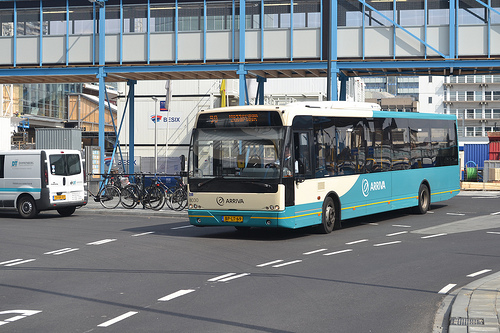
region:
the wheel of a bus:
[315, 190, 345, 235]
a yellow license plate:
[220, 208, 247, 226]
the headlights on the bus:
[260, 201, 282, 212]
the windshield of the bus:
[185, 122, 285, 183]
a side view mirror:
[175, 148, 190, 171]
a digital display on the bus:
[197, 107, 278, 128]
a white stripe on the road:
[152, 280, 199, 305]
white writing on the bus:
[352, 171, 392, 197]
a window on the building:
[462, 86, 477, 102]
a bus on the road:
[175, 97, 475, 237]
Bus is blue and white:
[177, 80, 466, 247]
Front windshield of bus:
[191, 125, 281, 190]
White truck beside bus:
[1, 150, 93, 218]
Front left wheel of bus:
[316, 193, 350, 236]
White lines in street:
[138, 215, 438, 311]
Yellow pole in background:
[203, 74, 235, 102]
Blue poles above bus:
[10, 0, 497, 81]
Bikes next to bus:
[101, 172, 186, 211]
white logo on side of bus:
[353, 168, 393, 199]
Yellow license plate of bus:
[218, 212, 249, 222]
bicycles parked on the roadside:
[100, 165, 184, 215]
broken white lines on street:
[143, 260, 290, 297]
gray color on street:
[82, 255, 177, 272]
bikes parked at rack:
[93, 170, 181, 207]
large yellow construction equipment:
[192, 65, 233, 102]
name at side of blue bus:
[335, 172, 400, 199]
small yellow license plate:
[206, 206, 263, 232]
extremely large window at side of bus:
[324, 116, 468, 188]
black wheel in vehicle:
[8, 189, 46, 224]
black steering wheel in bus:
[254, 149, 291, 184]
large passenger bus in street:
[166, 86, 468, 241]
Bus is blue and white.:
[176, 96, 468, 236]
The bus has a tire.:
[193, 97, 478, 250]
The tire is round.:
[313, 186, 346, 236]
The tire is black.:
[312, 188, 351, 245]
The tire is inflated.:
[308, 188, 350, 253]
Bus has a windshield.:
[176, 101, 296, 227]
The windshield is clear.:
[181, 102, 299, 227]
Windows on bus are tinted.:
[283, 108, 470, 238]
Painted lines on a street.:
[1, 172, 498, 330]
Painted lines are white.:
[0, 187, 499, 331]